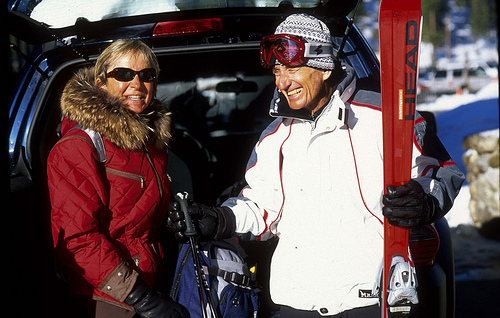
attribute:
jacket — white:
[181, 19, 463, 309]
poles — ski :
[169, 169, 232, 316]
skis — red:
[373, 7, 422, 317]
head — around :
[249, 10, 349, 115]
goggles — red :
[260, 36, 304, 65]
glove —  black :
[381, 172, 441, 234]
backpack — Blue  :
[183, 247, 255, 317]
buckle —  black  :
[217, 266, 245, 285]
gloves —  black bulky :
[371, 176, 442, 231]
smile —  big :
[266, 67, 325, 109]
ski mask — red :
[247, 31, 332, 65]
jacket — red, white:
[221, 62, 466, 314]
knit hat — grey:
[222, 9, 404, 85]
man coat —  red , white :
[231, 17, 493, 314]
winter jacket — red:
[43, 114, 188, 289]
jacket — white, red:
[248, 102, 414, 282]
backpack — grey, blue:
[172, 228, 256, 315]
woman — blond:
[46, 30, 180, 312]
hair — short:
[83, 32, 161, 91]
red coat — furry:
[45, 99, 186, 279]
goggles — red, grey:
[252, 27, 341, 77]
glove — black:
[382, 177, 446, 234]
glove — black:
[167, 192, 237, 242]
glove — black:
[125, 272, 190, 316]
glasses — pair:
[89, 60, 181, 92]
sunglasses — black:
[105, 65, 159, 82]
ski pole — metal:
[173, 191, 210, 316]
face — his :
[274, 60, 314, 108]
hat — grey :
[257, 9, 341, 78]